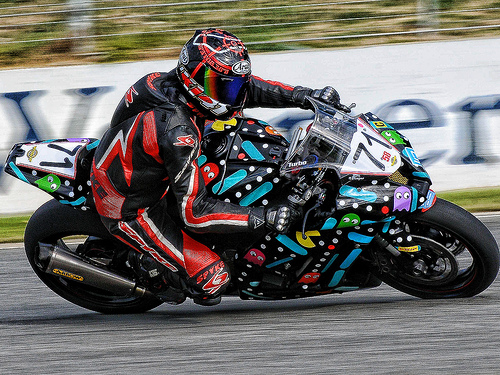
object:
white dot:
[259, 134, 265, 139]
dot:
[312, 269, 319, 273]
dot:
[301, 285, 308, 290]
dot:
[366, 205, 372, 212]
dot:
[324, 252, 331, 257]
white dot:
[237, 277, 243, 282]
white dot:
[265, 235, 271, 241]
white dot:
[224, 198, 231, 203]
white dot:
[81, 206, 87, 211]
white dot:
[248, 166, 255, 172]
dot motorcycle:
[0, 95, 500, 314]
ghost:
[336, 213, 360, 229]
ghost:
[380, 130, 407, 146]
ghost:
[244, 248, 266, 266]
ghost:
[298, 272, 321, 284]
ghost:
[34, 174, 61, 193]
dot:
[315, 264, 322, 268]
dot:
[32, 170, 38, 177]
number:
[39, 157, 74, 168]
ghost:
[392, 185, 412, 212]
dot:
[289, 254, 296, 258]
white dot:
[367, 228, 373, 233]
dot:
[320, 258, 326, 262]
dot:
[332, 238, 339, 244]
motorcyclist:
[90, 29, 341, 307]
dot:
[305, 274, 311, 278]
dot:
[339, 200, 346, 206]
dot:
[328, 245, 336, 251]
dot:
[371, 180, 378, 185]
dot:
[418, 197, 425, 203]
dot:
[313, 275, 319, 279]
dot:
[383, 182, 390, 188]